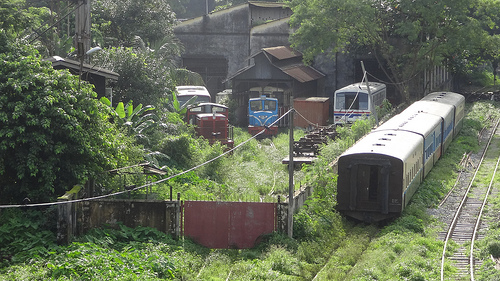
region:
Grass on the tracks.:
[352, 250, 426, 280]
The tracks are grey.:
[437, 206, 493, 238]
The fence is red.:
[191, 202, 268, 246]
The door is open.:
[343, 161, 395, 211]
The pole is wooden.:
[275, 145, 302, 221]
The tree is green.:
[312, 11, 384, 47]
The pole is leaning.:
[349, 68, 381, 104]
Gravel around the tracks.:
[434, 201, 472, 232]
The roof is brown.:
[254, 48, 319, 86]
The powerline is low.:
[21, 185, 116, 221]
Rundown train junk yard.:
[0, 2, 498, 279]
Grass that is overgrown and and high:
[2, 110, 496, 280]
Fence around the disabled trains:
[2, 38, 448, 249]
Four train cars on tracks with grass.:
[333, 70, 477, 242]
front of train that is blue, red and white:
[229, 75, 297, 148]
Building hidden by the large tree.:
[0, 19, 155, 202]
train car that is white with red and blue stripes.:
[327, 69, 388, 136]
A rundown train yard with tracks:
[1, 0, 498, 277]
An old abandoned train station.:
[95, 0, 462, 126]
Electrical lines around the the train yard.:
[0, 50, 473, 240]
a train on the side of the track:
[350, 106, 455, 212]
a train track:
[433, 209, 479, 238]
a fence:
[196, 206, 262, 238]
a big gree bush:
[7, 51, 98, 166]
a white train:
[333, 82, 364, 114]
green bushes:
[198, 160, 267, 198]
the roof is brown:
[271, 49, 328, 83]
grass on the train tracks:
[372, 243, 448, 278]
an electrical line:
[186, 153, 211, 173]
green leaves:
[115, 100, 175, 137]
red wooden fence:
[157, 176, 327, 244]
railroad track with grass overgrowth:
[411, 193, 482, 277]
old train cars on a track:
[297, 80, 466, 222]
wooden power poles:
[240, 83, 353, 250]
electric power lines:
[6, 43, 389, 230]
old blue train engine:
[218, 83, 304, 149]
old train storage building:
[169, 53, 369, 145]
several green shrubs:
[37, 94, 167, 259]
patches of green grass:
[118, 230, 393, 272]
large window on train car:
[317, 74, 383, 135]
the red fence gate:
[174, 197, 276, 257]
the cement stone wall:
[63, 197, 176, 247]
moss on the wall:
[57, 184, 172, 254]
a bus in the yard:
[332, 70, 388, 136]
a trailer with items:
[275, 112, 350, 173]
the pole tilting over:
[348, 54, 385, 130]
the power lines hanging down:
[290, 67, 372, 137]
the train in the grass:
[329, 77, 475, 249]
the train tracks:
[439, 161, 490, 280]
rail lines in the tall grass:
[295, 223, 380, 280]